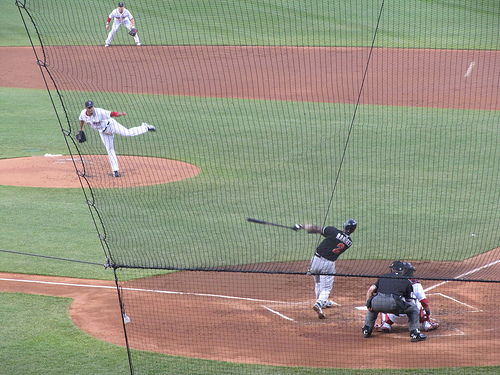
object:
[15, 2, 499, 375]
netting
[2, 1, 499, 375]
field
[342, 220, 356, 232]
helmet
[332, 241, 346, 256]
number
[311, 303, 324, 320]
shoe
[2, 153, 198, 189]
pitcher's mound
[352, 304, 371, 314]
home base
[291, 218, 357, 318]
batter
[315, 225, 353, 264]
jersey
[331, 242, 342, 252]
2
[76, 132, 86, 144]
glove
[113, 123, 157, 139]
left leg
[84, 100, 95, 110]
cap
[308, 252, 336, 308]
pants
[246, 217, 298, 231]
bat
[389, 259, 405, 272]
hat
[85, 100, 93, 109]
hat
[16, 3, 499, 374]
net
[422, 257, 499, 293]
line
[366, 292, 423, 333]
pants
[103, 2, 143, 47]
baseball player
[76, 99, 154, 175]
baseball player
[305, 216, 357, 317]
baseball player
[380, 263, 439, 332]
baseball player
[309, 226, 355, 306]
uniform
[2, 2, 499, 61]
outfield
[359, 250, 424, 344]
catcher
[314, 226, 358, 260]
back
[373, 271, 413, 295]
back